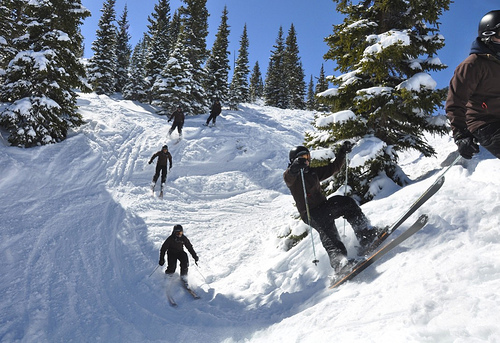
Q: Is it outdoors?
A: Yes, it is outdoors.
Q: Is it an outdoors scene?
A: Yes, it is outdoors.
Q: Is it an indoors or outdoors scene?
A: It is outdoors.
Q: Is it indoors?
A: No, it is outdoors.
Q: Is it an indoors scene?
A: No, it is outdoors.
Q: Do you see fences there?
A: No, there are no fences.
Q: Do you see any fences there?
A: No, there are no fences.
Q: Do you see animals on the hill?
A: No, there is a skier on the hill.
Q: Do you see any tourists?
A: No, there are no tourists.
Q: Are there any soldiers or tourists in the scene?
A: No, there are no tourists or soldiers.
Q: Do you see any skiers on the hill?
A: Yes, there is a skier on the hill.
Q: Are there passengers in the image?
A: No, there are no passengers.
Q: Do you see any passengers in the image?
A: No, there are no passengers.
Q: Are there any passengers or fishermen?
A: No, there are no passengers or fishermen.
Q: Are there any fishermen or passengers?
A: No, there are no passengers or fishermen.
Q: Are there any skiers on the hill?
A: Yes, there is a skier on the hill.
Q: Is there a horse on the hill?
A: No, there is a skier on the hill.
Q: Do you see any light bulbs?
A: No, there are no light bulbs.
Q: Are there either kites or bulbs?
A: No, there are no bulbs or kites.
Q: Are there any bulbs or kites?
A: No, there are no bulbs or kites.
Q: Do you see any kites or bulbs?
A: No, there are no bulbs or kites.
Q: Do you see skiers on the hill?
A: Yes, there is a skier on the hill.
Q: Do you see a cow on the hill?
A: No, there is a skier on the hill.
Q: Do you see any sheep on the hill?
A: No, there is a skier on the hill.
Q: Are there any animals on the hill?
A: No, there is a skier on the hill.